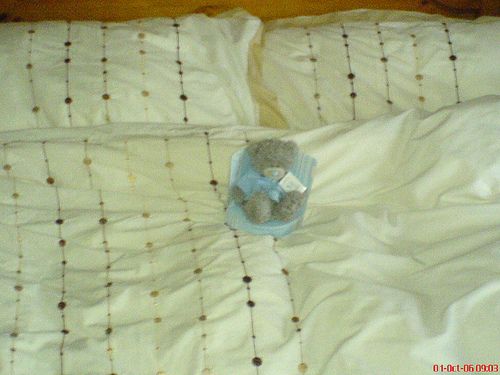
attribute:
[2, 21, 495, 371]
blanket — blue 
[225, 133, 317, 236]
fur — brown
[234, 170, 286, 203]
shirt — blue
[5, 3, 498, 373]
buscomforter — big, white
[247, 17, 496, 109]
pillow — big, fluffy, white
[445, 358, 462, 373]
letters — Red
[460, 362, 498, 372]
numbers — Red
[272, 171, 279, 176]
nose — blue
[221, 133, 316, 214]
teddy bear — small